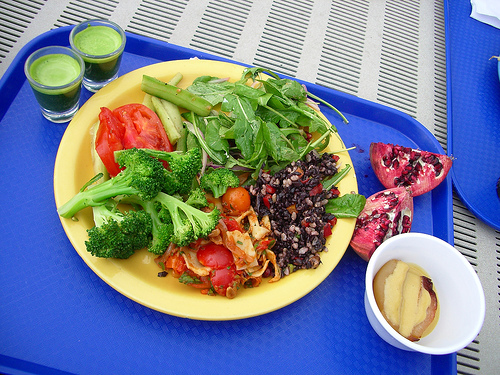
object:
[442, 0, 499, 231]
tray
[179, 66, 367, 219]
spinach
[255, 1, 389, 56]
table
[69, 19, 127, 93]
container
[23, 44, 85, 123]
container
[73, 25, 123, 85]
salad dressing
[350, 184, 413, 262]
pomegranate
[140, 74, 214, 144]
celery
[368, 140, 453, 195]
pomegranate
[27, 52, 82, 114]
beverage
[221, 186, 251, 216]
cherry tomato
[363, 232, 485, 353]
bowl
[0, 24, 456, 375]
tray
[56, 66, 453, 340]
food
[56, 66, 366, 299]
salad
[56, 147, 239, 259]
broccoli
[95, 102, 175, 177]
tomato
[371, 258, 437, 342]
dessert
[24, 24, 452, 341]
lunch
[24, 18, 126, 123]
shot glasses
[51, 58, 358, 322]
plate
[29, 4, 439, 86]
stand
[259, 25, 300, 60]
holes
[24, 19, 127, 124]
glasses